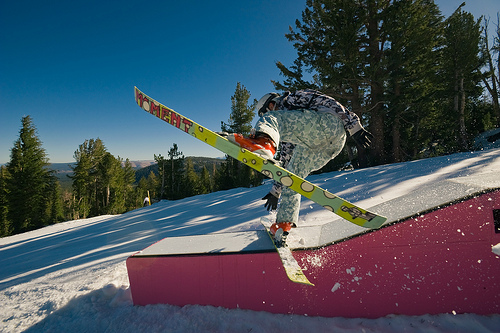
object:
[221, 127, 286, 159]
boots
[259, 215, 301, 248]
boots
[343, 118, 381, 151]
gloves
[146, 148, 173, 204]
trees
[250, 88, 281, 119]
helmet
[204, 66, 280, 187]
trees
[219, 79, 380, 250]
man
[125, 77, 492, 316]
trick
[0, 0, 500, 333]
landscape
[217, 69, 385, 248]
tricks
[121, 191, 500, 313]
pink side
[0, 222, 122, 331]
snow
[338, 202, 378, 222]
design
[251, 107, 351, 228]
camoflage pants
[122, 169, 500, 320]
pink platform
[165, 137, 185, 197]
many evergreen/trees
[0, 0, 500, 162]
blue sky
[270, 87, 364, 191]
ski jacket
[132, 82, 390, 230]
colorful skis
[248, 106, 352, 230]
skier's pants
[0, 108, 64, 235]
evergreen trees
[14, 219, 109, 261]
snow